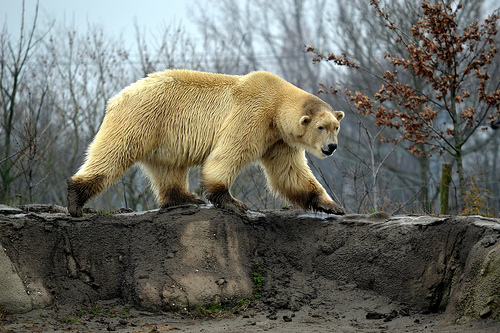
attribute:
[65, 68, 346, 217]
polar bear — furry, white, big, prowling, dirty, light brown, looking, shaggy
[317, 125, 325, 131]
eye — dark, small, round, beady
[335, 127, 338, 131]
eye — dark, small, round, beady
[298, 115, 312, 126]
ear — small, furry, little, round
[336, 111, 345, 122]
ear — small, furry, little, round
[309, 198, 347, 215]
paw — muddy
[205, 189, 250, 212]
paw — muddy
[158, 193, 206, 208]
paw — muddy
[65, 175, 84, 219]
paw — muddy, back, furry, brown, walking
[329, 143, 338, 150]
nose — black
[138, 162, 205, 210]
leg — hind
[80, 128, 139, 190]
leg — hind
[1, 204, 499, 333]
dirt — grey, wet, muddy, rocky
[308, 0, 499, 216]
tree — leafy, short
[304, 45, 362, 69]
leaves — dry, brown, dead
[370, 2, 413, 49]
leaves — dry, brown, dead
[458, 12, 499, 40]
leaves — dry, brown, dead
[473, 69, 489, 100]
leaves — dry, brown, dead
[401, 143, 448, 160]
leaves — dry, brown, dead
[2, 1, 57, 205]
tree — bare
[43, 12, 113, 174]
tree — bare, dark, thin, leafless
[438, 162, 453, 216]
pole — wood, green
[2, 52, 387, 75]
power lines — above, in air, for telephone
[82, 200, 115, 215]
grass — green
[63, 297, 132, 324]
grass — green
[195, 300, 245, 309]
grass — green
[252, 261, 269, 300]
grass — green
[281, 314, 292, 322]
rock — small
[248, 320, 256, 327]
rock — small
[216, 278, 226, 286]
rock — small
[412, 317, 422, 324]
rock — small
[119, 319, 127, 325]
rock — small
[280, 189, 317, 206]
fur — dark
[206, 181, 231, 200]
fur — dark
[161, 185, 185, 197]
fur — dark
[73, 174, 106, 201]
fur — dark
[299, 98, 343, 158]
head — turned right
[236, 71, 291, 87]
hump — furry